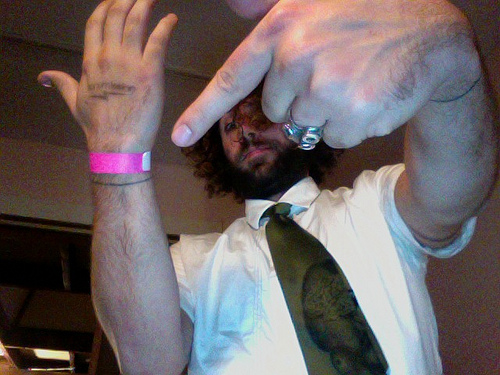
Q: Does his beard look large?
A: Yes, the beard is large.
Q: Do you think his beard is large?
A: Yes, the beard is large.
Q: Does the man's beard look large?
A: Yes, the beard is large.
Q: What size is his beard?
A: The beard is large.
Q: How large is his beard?
A: The beard is large.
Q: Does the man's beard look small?
A: No, the beard is large.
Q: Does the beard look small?
A: No, the beard is large.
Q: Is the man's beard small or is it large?
A: The beard is large.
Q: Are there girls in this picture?
A: No, there are no girls.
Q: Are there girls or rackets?
A: No, there are no girls or rackets.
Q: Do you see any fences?
A: No, there are no fences.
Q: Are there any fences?
A: No, there are no fences.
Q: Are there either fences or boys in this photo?
A: No, there are no fences or boys.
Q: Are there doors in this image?
A: Yes, there is a door.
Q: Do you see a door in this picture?
A: Yes, there is a door.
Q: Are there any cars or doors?
A: Yes, there is a door.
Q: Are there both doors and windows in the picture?
A: No, there is a door but no windows.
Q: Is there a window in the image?
A: No, there are no windows.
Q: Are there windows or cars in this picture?
A: No, there are no windows or cars.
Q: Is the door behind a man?
A: Yes, the door is behind a man.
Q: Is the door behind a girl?
A: No, the door is behind a man.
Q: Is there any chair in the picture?
A: No, there are no chairs.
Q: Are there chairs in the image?
A: No, there are no chairs.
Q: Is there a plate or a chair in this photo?
A: No, there are no chairs or plates.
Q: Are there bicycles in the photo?
A: No, there are no bicycles.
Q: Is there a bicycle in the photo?
A: No, there are no bicycles.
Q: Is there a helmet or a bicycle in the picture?
A: No, there are no bicycles or helmets.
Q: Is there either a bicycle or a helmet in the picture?
A: No, there are no bicycles or helmets.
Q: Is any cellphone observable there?
A: No, there are no cell phones.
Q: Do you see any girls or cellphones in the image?
A: No, there are no cellphones or girls.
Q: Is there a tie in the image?
A: Yes, there is a tie.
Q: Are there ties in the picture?
A: Yes, there is a tie.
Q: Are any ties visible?
A: Yes, there is a tie.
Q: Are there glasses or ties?
A: Yes, there is a tie.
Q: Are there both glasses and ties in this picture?
A: Yes, there are both a tie and glasses.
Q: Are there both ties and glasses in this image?
A: Yes, there are both a tie and glasses.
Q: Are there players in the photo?
A: No, there are no players.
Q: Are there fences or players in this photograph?
A: No, there are no players or fences.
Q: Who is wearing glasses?
A: The man is wearing glasses.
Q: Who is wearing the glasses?
A: The man is wearing glasses.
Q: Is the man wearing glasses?
A: Yes, the man is wearing glasses.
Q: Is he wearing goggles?
A: No, the man is wearing glasses.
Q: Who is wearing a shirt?
A: The man is wearing a shirt.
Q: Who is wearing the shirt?
A: The man is wearing a shirt.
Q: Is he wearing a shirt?
A: Yes, the man is wearing a shirt.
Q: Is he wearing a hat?
A: No, the man is wearing a shirt.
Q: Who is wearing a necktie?
A: The man is wearing a necktie.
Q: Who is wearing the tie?
A: The man is wearing a necktie.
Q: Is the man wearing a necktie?
A: Yes, the man is wearing a necktie.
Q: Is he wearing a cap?
A: No, the man is wearing a necktie.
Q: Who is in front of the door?
A: The man is in front of the door.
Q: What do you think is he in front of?
A: The man is in front of the door.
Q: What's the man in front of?
A: The man is in front of the door.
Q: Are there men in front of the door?
A: Yes, there is a man in front of the door.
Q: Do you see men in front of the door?
A: Yes, there is a man in front of the door.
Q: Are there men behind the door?
A: No, the man is in front of the door.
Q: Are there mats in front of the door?
A: No, there is a man in front of the door.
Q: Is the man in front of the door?
A: Yes, the man is in front of the door.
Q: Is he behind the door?
A: No, the man is in front of the door.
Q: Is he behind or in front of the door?
A: The man is in front of the door.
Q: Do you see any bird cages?
A: No, there are no bird cages.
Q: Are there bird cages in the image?
A: No, there are no bird cages.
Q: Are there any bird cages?
A: No, there are no bird cages.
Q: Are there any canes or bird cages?
A: No, there are no bird cages or canes.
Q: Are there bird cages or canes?
A: No, there are no bird cages or canes.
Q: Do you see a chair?
A: No, there are no chairs.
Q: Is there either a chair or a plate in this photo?
A: No, there are no chairs or plates.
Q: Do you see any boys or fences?
A: No, there are no fences or boys.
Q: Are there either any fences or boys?
A: No, there are no fences or boys.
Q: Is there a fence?
A: No, there are no fences.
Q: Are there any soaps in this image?
A: No, there are no soaps.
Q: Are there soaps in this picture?
A: No, there are no soaps.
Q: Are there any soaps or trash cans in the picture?
A: No, there are no soaps or trash cans.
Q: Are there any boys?
A: No, there are no boys.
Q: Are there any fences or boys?
A: No, there are no boys or fences.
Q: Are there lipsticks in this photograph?
A: No, there are no lipsticks.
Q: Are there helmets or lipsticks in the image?
A: No, there are no lipsticks or helmets.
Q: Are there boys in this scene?
A: No, there are no boys.